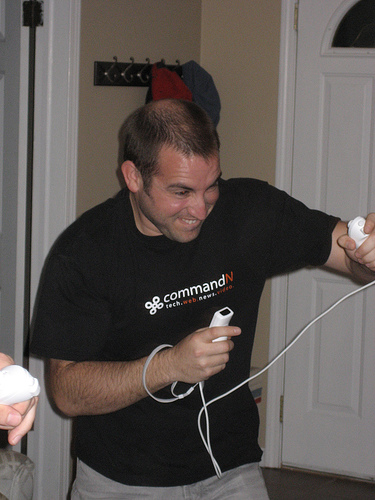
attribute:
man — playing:
[25, 94, 373, 498]